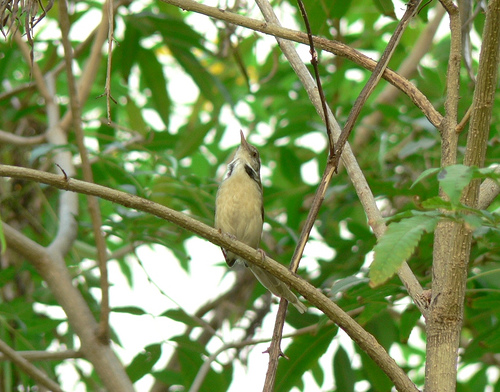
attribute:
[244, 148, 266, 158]
eye — black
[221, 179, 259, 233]
feathers — yellow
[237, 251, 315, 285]
foot — right foot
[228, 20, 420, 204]
branches — brown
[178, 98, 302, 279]
bird — little, looking upward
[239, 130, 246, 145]
beak — little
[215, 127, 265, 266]
bird — white, black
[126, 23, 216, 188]
leaves — green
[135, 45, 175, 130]
leaf — green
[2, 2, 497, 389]
tree — green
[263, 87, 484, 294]
leaves — green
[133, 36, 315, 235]
leaves — green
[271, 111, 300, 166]
leaf — green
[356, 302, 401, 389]
leaf — bright, green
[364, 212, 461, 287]
leaf — bright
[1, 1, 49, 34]
branches — brown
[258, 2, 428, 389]
branch — brown, dark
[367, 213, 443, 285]
leaf — bright, green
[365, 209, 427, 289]
leaf — green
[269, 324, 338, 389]
leaf — green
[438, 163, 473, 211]
leaf — green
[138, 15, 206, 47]
leaf — green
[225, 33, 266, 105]
leaf — green